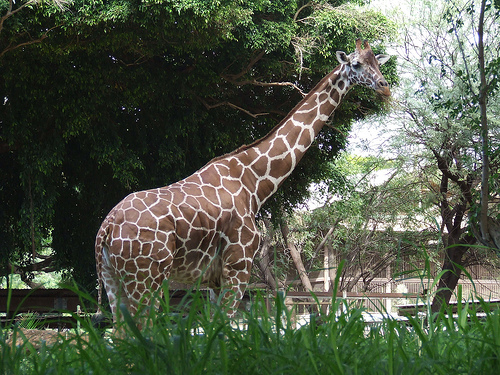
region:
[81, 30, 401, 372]
Giraffe is very tall.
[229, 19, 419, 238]
Giraffe has a long neck.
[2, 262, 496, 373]
Grass is overgrown.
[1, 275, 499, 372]
Grass is green.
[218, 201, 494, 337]
Building in the background.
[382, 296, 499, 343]
Bench on other side of tree.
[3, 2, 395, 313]
Leaves on the tree are green.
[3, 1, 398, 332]
Tree is tall and full.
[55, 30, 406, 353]
Giraffe has brown patches.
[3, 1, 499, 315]
Giraffe is outside.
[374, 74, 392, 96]
nostril of a giraffe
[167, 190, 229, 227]
spots on a giraffe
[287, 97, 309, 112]
short mane on a giraffe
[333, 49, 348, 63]
ear of a giraffe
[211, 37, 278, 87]
a tree branch with leaves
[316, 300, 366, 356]
blades of green grass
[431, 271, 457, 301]
trunk of a tree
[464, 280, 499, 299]
white railing with posts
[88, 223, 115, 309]
the tail of a giraffe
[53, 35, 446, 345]
a giraffe standing in front of a tree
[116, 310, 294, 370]
the grass is green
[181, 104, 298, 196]
the giraffe is brown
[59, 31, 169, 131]
tree's leaves are green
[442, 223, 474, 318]
the branch is brown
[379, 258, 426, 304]
the wall is brown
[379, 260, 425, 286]
the wall is made of wood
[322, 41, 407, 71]
giraffe has two ears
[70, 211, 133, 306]
the giraffe has tail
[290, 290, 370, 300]
the fence is brown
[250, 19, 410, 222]
the giraffe's neck is long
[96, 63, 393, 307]
the giraffe is very tall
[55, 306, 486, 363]
the grass is green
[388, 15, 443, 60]
the sky is cloudy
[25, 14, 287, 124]
the tree has many leaves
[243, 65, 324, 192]
the neck is very long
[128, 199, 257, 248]
the skin is very beautiful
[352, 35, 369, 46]
the giraffe has small horns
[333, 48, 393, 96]
the giraffe has two ears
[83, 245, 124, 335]
the tail is very short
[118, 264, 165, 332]
the behind leg is thick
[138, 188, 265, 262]
The giraffe has brown spots.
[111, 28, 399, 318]
The giraffe is tall as the trees.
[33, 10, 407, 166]
trees sit behind the giraffe.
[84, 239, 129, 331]
The giraffe tail is long.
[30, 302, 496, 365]
The green plants are in front of the giraffe.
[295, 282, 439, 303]
The railing on the fence is brown.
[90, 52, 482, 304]
The giraffe is standing next to the tree.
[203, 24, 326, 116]
The tree branches are hanging.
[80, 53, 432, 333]
The giraffe is standing behind the gate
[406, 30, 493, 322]
The tree leaves are green.